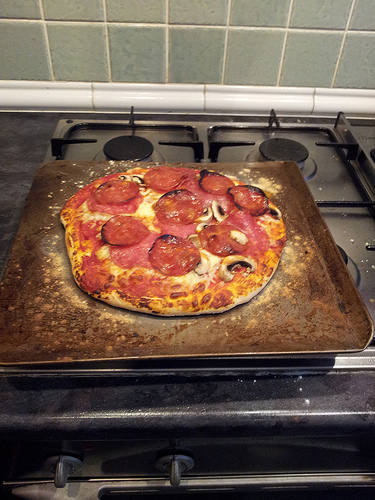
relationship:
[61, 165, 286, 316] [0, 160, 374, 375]
pizza on pan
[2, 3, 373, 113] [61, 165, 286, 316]
wall above pizza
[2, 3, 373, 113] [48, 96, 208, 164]
wall above burner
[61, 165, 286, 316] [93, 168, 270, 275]
pizza has toppings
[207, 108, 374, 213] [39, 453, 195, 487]
burner has knobs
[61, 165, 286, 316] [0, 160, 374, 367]
pizza on pan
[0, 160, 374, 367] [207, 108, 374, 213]
pan sitting on burner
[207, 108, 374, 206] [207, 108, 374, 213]
burner on burner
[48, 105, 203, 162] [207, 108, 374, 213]
burner on burner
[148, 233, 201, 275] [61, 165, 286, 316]
pepperoni on pizza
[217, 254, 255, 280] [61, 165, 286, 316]
mushroom on pizza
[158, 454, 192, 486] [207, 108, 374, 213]
knob on front of burner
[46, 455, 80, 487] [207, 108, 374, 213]
knob on front of burner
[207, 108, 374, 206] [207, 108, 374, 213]
burner on back of burner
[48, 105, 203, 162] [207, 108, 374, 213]
burner on back of burner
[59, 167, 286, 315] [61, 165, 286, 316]
crust on pizza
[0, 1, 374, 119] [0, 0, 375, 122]
tiles on backsplash